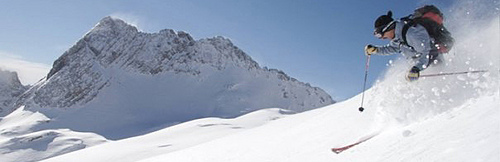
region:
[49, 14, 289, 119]
snow covered mountain in the distance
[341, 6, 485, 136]
skier racing down the slope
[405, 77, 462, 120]
snow kicked up from the skis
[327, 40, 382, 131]
ski pole in the air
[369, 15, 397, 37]
goggles on the skier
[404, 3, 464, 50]
backpack on the skier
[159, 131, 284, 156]
snow covered ski slope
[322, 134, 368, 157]
ski on top of the snow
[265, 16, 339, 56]
powder blue sky above the mountain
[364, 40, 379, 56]
glove on the skier's hand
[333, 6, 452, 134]
the man is skiing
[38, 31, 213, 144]
a snow covered mountain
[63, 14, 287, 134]
a snow covered mountain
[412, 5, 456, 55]
the orange and black backpack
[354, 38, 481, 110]
the skiers ski poles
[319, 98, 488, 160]
the skies on his feet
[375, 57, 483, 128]
the snow being tossed up by the skier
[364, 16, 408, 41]
the goggles on his face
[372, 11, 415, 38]
the hat on his head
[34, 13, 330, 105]
the mountain in the background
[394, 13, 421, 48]
the straps on his shoulders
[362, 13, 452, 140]
the skier sking down the hill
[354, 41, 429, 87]
the gloves on his hands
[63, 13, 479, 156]
this man is sking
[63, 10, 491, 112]
sking down a mountain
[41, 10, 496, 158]
the snow is fresh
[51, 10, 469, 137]
fresh snow is powder spray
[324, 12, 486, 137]
the skier has a backpack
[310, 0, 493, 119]
the skier has two poles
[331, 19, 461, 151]
the jacket is blue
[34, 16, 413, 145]
the sky is clear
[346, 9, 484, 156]
he has two poles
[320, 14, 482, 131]
the skier is male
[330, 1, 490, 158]
Man skiing on the slope.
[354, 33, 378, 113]
Ski pole in the hand.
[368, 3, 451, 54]
Back pack on the man.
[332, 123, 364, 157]
Red ski on the snow.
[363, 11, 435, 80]
Gray jacket on the man.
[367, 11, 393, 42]
Black hat on the man.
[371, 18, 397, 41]
Goggles on the man.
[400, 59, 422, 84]
Black glove on the hand.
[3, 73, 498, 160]
White snow covering the ground.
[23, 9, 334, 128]
Mountain in the background.